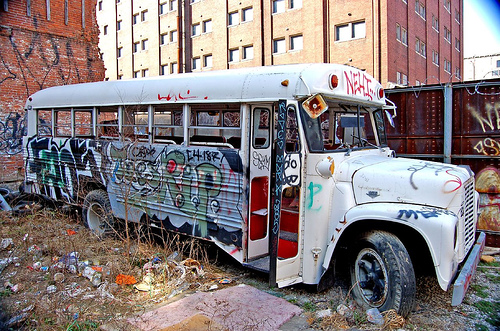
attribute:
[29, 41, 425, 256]
bus — blue, white, side, red, hood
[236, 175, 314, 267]
door — red, open, bus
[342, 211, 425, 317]
tire — old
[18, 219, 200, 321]
trash — laying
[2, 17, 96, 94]
graffiti — black, brick, wooden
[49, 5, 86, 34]
brick — red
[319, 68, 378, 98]
letter — red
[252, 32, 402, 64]
building — brick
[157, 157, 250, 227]
word — black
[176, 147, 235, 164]
letter — black